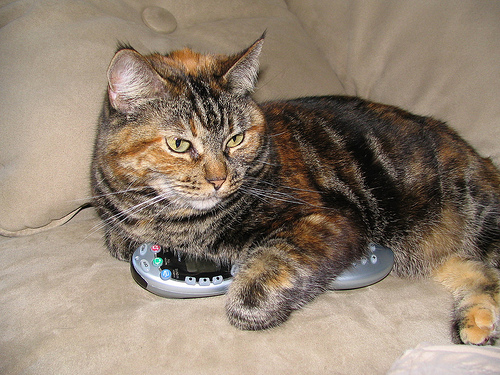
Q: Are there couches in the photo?
A: Yes, there is a couch.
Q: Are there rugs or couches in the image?
A: Yes, there is a couch.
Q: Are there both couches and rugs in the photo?
A: No, there is a couch but no rugs.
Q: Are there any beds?
A: No, there are no beds.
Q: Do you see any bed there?
A: No, there are no beds.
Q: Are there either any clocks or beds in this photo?
A: No, there are no beds or clocks.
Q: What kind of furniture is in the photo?
A: The furniture is a couch.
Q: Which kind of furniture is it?
A: The piece of furniture is a couch.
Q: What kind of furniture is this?
A: This is a couch.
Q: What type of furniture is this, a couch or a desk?
A: This is a couch.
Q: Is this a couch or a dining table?
A: This is a couch.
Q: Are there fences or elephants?
A: No, there are no fences or elephants.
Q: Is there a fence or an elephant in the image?
A: No, there are no fences or elephants.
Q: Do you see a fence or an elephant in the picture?
A: No, there are no fences or elephants.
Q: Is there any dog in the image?
A: No, there are no dogs.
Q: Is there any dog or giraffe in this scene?
A: No, there are no dogs or giraffes.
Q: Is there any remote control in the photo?
A: Yes, there is a remote control.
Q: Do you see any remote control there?
A: Yes, there is a remote control.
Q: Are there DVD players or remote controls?
A: Yes, there is a remote control.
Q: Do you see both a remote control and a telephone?
A: No, there is a remote control but no phones.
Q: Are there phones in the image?
A: No, there are no phones.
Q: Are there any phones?
A: No, there are no phones.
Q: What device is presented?
A: The device is a remote control.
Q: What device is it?
A: The device is a remote control.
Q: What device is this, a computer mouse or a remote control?
A: This is a remote control.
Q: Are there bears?
A: No, there are no bears.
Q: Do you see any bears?
A: No, there are no bears.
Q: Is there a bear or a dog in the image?
A: No, there are no bears or dogs.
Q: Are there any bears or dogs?
A: No, there are no bears or dogs.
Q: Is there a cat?
A: Yes, there is a cat.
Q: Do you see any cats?
A: Yes, there is a cat.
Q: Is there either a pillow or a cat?
A: Yes, there is a cat.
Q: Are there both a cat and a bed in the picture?
A: No, there is a cat but no beds.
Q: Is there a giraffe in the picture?
A: No, there are no giraffes.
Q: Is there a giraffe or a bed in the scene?
A: No, there are no giraffes or beds.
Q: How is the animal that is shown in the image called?
A: The animal is a cat.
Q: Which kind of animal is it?
A: The animal is a cat.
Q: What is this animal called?
A: This is a cat.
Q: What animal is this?
A: This is a cat.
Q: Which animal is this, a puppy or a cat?
A: This is a cat.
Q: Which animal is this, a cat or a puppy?
A: This is a cat.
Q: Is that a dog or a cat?
A: That is a cat.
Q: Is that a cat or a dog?
A: That is a cat.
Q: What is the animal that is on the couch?
A: The animal is a cat.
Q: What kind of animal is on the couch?
A: The animal is a cat.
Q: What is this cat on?
A: The cat is on the couch.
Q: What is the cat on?
A: The cat is on the couch.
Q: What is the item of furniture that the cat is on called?
A: The piece of furniture is a couch.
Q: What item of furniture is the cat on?
A: The cat is on the couch.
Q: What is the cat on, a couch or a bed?
A: The cat is on a couch.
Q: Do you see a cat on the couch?
A: Yes, there is a cat on the couch.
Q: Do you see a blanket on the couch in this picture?
A: No, there is a cat on the couch.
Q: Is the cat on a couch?
A: Yes, the cat is on a couch.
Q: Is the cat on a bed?
A: No, the cat is on a couch.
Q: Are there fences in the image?
A: No, there are no fences.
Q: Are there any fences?
A: No, there are no fences.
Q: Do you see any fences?
A: No, there are no fences.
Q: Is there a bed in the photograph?
A: No, there are no beds.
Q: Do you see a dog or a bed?
A: No, there are no beds or dogs.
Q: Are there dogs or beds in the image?
A: No, there are no beds or dogs.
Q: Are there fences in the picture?
A: No, there are no fences.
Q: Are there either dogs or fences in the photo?
A: No, there are no fences or dogs.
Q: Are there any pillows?
A: Yes, there is a pillow.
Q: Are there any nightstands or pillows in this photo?
A: Yes, there is a pillow.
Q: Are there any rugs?
A: No, there are no rugs.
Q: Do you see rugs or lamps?
A: No, there are no rugs or lamps.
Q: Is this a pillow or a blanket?
A: This is a pillow.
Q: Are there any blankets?
A: No, there are no blankets.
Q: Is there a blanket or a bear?
A: No, there are no blankets or bears.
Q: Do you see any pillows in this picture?
A: Yes, there is a pillow.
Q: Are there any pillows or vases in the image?
A: Yes, there is a pillow.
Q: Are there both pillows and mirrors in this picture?
A: No, there is a pillow but no mirrors.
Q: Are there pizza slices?
A: No, there are no pizza slices.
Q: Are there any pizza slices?
A: No, there are no pizza slices.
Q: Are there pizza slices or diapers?
A: No, there are no pizza slices or diapers.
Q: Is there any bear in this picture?
A: No, there are no bears.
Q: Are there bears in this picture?
A: No, there are no bears.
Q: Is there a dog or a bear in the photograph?
A: No, there are no bears or dogs.